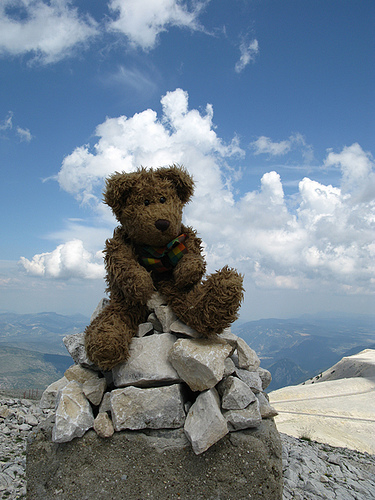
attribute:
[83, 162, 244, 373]
teddy bear — brown, shaggy, fuzzy, plush, messy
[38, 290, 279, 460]
rocks — white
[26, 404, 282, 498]
base — concrete, stone, gray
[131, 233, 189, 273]
ribbon — multicolored, plaid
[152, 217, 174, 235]
nose — dark brown, black, brown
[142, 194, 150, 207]
eye — black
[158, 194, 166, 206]
eye — black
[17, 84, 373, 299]
cloud — white, puffy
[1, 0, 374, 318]
sky — blue, beautiful, cloudy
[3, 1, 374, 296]
clouds — fluffy, white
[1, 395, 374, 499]
rocks — grey, slate, white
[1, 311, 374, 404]
mountains — below, far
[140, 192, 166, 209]
eyes — beady, black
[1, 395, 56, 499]
rocks — small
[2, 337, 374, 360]
road — white